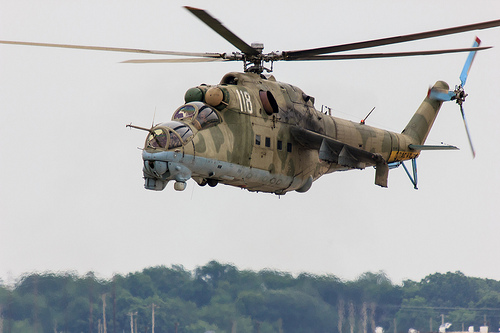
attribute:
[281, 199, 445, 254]
clouds — are white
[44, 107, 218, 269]
sky — is blue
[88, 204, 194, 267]
clouds — are white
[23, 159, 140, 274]
clouds — are white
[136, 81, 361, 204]
helicopter — is camo-colored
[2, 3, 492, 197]
helicopter — camouflage painted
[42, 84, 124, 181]
sky — blue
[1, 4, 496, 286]
sky — is blue, clear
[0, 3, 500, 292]
clouds — are white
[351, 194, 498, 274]
cloud — white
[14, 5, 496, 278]
cloud — white